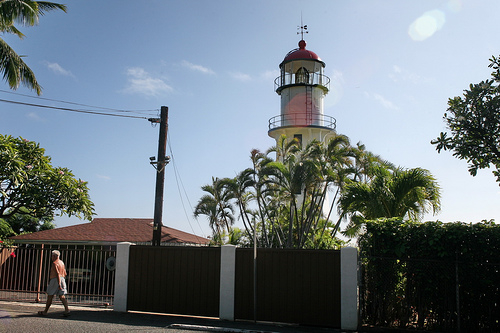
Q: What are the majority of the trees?
A: Palm.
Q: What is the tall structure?
A: Lighthouse.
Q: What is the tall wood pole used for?
A: Utility lines.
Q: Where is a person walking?
A: In front of the gate.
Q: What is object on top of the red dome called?
A: Weathervane.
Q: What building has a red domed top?
A: The white lighthouse.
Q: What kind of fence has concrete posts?
A: A privacy fence.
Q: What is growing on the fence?
A: Shrubs.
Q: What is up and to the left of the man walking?
A: A green tree.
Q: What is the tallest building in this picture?
A: Red and white light house.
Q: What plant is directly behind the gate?
A: Palm trees.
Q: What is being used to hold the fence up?
A: Large white posts.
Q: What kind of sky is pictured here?
A: Blue sky with a few clouds.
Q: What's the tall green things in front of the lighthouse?
A: Palm trees.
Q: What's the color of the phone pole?
A: Brown.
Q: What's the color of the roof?
A: Red.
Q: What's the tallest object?
A: Light tower.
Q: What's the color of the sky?
A: Blue.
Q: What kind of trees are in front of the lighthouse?
A: Palm trees.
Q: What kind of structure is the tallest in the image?
A: The lightouse.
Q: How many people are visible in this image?
A: One.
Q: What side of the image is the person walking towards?
A: Left.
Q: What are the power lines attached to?
A: Telephone pole.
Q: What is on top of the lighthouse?
A: A weathervane.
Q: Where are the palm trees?
A: Behind the fence.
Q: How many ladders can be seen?
A: One.